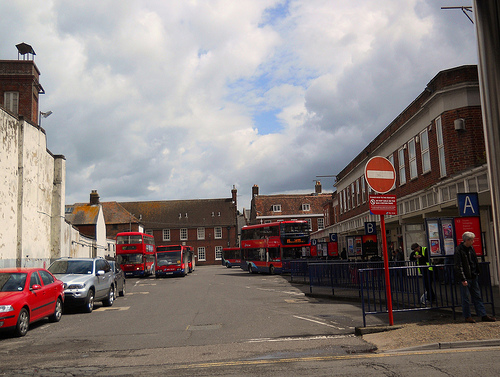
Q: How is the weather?
A: Cloudy.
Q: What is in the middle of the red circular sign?
A: White line.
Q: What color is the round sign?
A: Red.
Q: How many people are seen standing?
A: 2.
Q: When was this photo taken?
A: Daytime.